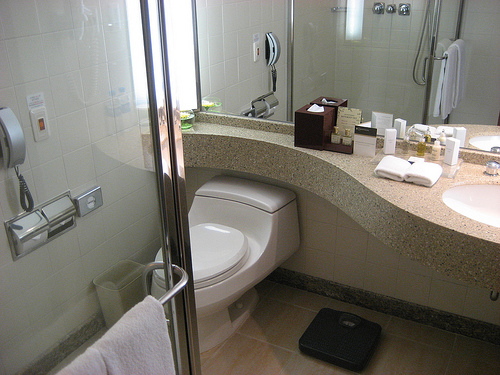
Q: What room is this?
A: Bathroom.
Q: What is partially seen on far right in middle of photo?
A: Sink.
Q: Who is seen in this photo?
A: No One.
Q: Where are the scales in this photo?
A: On floor.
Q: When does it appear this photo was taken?
A: Daytime.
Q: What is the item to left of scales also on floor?
A: Commode.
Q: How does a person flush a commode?
A: With handle.